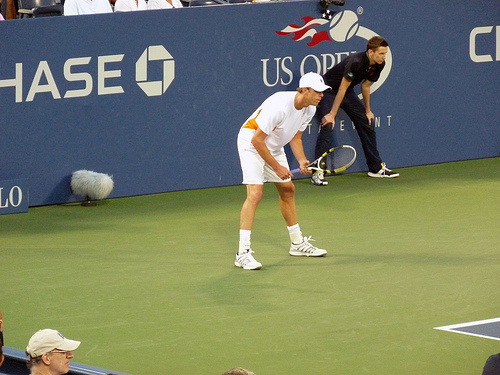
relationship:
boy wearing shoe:
[309, 31, 404, 185] [209, 228, 344, 294]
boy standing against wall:
[310, 31, 404, 182] [391, 0, 498, 160]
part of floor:
[233, 289, 269, 310] [179, 270, 398, 348]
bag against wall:
[68, 169, 120, 206] [0, 0, 498, 207]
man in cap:
[24, 328, 82, 375] [27, 331, 80, 358]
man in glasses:
[24, 328, 82, 375] [36, 347, 72, 358]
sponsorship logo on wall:
[0, 43, 177, 102] [0, 0, 498, 207]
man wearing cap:
[233, 72, 327, 271] [300, 70, 331, 93]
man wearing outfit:
[231, 62, 342, 281] [243, 88, 318, 195]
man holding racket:
[233, 72, 327, 271] [291, 145, 357, 174]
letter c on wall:
[467, 25, 492, 63] [0, 0, 498, 207]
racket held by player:
[284, 141, 359, 185] [231, 68, 329, 273]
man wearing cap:
[24, 328, 82, 375] [27, 328, 80, 358]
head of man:
[23, 329, 81, 373] [24, 328, 82, 375]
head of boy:
[359, 35, 386, 63] [309, 31, 404, 185]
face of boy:
[370, 37, 390, 69] [309, 31, 404, 185]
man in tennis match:
[24, 328, 82, 375] [2, 0, 495, 374]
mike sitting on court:
[64, 164, 117, 198] [0, 153, 496, 369]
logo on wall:
[256, 8, 408, 140] [0, 0, 498, 207]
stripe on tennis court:
[432, 313, 498, 348] [433, 315, 498, 355]